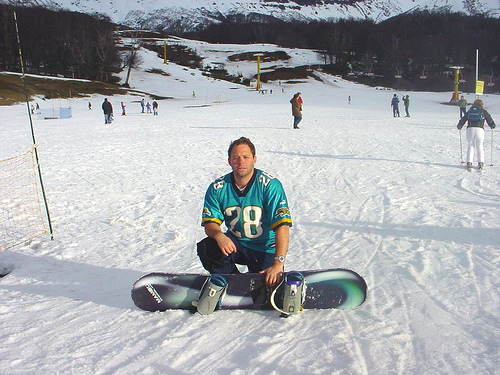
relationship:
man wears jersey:
[221, 128, 278, 206] [208, 180, 279, 247]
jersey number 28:
[193, 173, 298, 269] [218, 202, 264, 239]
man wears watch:
[195, 136, 292, 285] [269, 253, 289, 266]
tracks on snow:
[304, 181, 486, 282] [218, 100, 470, 235]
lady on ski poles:
[457, 99, 496, 169] [455, 120, 499, 178]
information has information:
[475, 81, 484, 93] [475, 80, 482, 90]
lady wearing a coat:
[457, 99, 496, 169] [455, 108, 495, 129]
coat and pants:
[455, 108, 495, 129] [463, 129, 485, 165]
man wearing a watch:
[195, 136, 292, 285] [269, 252, 287, 266]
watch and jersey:
[269, 252, 287, 266] [201, 167, 292, 253]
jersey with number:
[201, 167, 292, 253] [224, 203, 264, 237]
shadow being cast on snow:
[296, 215, 498, 247] [0, 0, 499, 374]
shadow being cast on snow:
[1, 250, 152, 307] [0, 0, 499, 374]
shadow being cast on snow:
[265, 147, 464, 168] [0, 0, 499, 374]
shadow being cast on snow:
[188, 124, 290, 131] [0, 0, 499, 374]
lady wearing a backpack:
[457, 99, 496, 169] [463, 108, 483, 120]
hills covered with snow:
[2, 0, 499, 97] [3, 0, 499, 99]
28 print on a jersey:
[224, 205, 264, 238] [194, 167, 291, 247]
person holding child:
[289, 92, 302, 126] [293, 92, 307, 107]